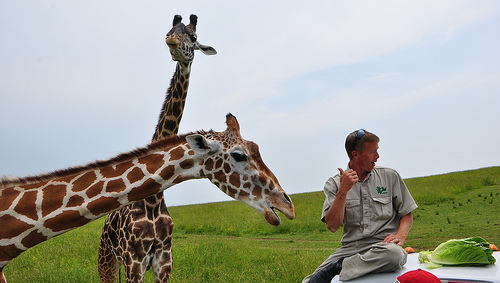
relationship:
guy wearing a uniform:
[301, 128, 420, 283] [303, 166, 418, 282]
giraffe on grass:
[1, 113, 295, 282] [0, 165, 500, 282]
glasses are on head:
[349, 129, 369, 148] [346, 129, 382, 174]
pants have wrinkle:
[301, 240, 407, 282] [358, 253, 383, 264]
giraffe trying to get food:
[1, 113, 295, 282] [419, 235, 499, 268]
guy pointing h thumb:
[301, 128, 421, 282] [337, 168, 346, 178]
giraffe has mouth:
[1, 113, 295, 282] [271, 206, 292, 223]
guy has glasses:
[301, 128, 421, 282] [349, 129, 369, 148]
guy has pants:
[301, 128, 421, 282] [301, 240, 407, 282]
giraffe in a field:
[1, 113, 295, 282] [4, 166, 499, 282]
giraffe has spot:
[1, 113, 295, 282] [14, 192, 38, 220]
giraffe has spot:
[1, 113, 295, 282] [43, 184, 66, 217]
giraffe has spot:
[1, 113, 295, 282] [71, 172, 96, 192]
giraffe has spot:
[1, 113, 295, 282] [98, 162, 136, 178]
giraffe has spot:
[1, 113, 295, 282] [139, 153, 166, 174]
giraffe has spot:
[1, 113, 295, 282] [170, 147, 185, 161]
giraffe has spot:
[1, 113, 295, 282] [180, 160, 195, 171]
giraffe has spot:
[1, 113, 295, 282] [159, 164, 177, 181]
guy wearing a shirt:
[301, 128, 420, 283] [321, 168, 427, 241]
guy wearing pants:
[301, 128, 420, 283] [301, 240, 407, 282]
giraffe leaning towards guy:
[1, 113, 295, 282] [301, 128, 420, 283]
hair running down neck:
[2, 130, 207, 187] [1, 132, 205, 270]